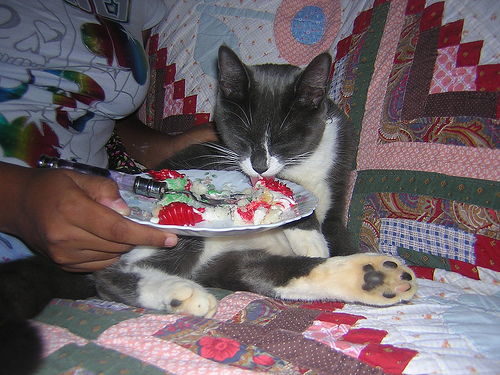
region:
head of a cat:
[182, 35, 368, 181]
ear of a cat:
[199, 52, 283, 112]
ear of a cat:
[266, 33, 357, 118]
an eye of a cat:
[223, 120, 265, 158]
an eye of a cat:
[280, 110, 317, 152]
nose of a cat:
[238, 152, 280, 181]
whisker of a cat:
[188, 145, 241, 175]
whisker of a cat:
[276, 134, 331, 184]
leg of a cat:
[303, 242, 436, 312]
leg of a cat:
[132, 250, 247, 307]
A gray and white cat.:
[97, 43, 416, 319]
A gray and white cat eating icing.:
[9, 42, 420, 368]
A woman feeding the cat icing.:
[10, 1, 433, 357]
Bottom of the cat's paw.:
[326, 249, 425, 305]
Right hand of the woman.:
[0, 154, 179, 279]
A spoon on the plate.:
[40, 148, 241, 214]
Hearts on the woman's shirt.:
[4, 8, 64, 58]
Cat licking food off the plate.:
[205, 43, 345, 209]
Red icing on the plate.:
[154, 199, 211, 230]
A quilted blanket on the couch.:
[106, 0, 471, 371]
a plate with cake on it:
[115, 170, 317, 237]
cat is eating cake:
[214, 47, 330, 192]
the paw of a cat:
[358, 253, 412, 305]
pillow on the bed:
[145, 0, 497, 293]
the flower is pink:
[198, 334, 238, 360]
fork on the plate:
[38, 159, 239, 209]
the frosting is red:
[160, 201, 202, 224]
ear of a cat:
[300, 51, 332, 95]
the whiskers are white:
[192, 139, 238, 169]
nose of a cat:
[251, 163, 268, 171]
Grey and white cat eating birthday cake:
[102, 48, 354, 233]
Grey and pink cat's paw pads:
[347, 249, 418, 310]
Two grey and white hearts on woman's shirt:
[12, 9, 67, 62]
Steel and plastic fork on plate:
[35, 157, 238, 217]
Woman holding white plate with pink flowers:
[12, 169, 319, 274]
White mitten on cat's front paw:
[279, 223, 330, 264]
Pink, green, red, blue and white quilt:
[30, 5, 495, 372]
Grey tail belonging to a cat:
[0, 252, 95, 374]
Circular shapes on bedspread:
[272, 0, 344, 70]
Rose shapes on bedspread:
[187, 327, 274, 373]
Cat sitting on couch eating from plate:
[91, 46, 417, 326]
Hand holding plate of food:
[0, 165, 320, 284]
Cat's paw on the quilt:
[341, 248, 417, 310]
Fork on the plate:
[32, 160, 247, 206]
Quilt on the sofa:
[25, 0, 495, 372]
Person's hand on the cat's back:
[130, 120, 220, 170]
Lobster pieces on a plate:
[105, 165, 312, 235]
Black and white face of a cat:
[205, 41, 332, 177]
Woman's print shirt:
[0, 0, 153, 255]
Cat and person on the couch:
[1, 0, 425, 321]